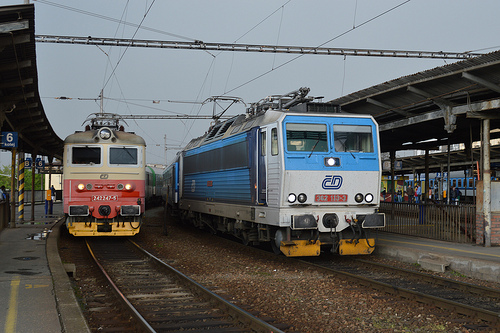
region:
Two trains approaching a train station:
[60, 110, 404, 330]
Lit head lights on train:
[281, 185, 378, 208]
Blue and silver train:
[170, 113, 387, 235]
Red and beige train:
[61, 129, 153, 216]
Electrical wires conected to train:
[58, 3, 338, 141]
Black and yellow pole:
[7, 148, 32, 226]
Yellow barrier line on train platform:
[1, 266, 29, 326]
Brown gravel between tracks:
[208, 261, 370, 328]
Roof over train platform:
[1, 5, 61, 162]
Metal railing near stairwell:
[403, 197, 480, 247]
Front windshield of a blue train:
[283, 120, 375, 161]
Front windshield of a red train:
[62, 140, 143, 170]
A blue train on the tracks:
[168, 98, 386, 253]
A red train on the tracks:
[50, 118, 162, 240]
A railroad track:
[83, 251, 260, 327]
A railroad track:
[367, 266, 464, 331]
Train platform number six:
[0, 126, 32, 158]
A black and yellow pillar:
[13, 155, 28, 229]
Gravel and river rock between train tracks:
[268, 274, 335, 317]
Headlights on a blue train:
[290, 158, 375, 205]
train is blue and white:
[164, 105, 409, 288]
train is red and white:
[50, 122, 164, 292]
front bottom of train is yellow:
[56, 207, 393, 289]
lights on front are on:
[281, 143, 390, 240]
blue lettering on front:
[317, 176, 352, 196]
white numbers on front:
[85, 186, 134, 207]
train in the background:
[411, 167, 478, 201]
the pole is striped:
[10, 142, 32, 226]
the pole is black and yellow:
[14, 154, 29, 222]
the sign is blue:
[3, 122, 19, 149]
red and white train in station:
[62, 140, 139, 245]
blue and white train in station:
[190, 130, 382, 222]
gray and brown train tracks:
[99, 258, 234, 313]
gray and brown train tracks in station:
[90, 253, 195, 312]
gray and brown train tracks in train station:
[102, 265, 223, 319]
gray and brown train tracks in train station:
[364, 257, 417, 294]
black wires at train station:
[86, 18, 360, 68]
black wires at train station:
[282, 38, 399, 63]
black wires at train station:
[144, 103, 175, 121]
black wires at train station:
[56, 6, 196, 38]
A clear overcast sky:
[158, 61, 183, 88]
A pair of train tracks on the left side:
[111, 277, 236, 321]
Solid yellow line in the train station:
[5, 282, 27, 324]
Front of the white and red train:
[67, 138, 140, 233]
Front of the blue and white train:
[284, 122, 380, 221]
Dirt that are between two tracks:
[258, 267, 312, 309]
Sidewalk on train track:
[15, 235, 33, 271]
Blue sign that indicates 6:
[5, 131, 17, 144]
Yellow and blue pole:
[11, 158, 30, 230]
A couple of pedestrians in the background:
[406, 185, 425, 200]